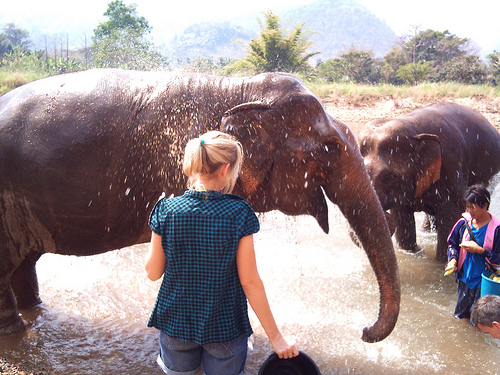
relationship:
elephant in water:
[355, 94, 491, 269] [11, 243, 499, 372]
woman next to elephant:
[139, 125, 303, 372] [5, 60, 404, 351]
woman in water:
[139, 125, 303, 372] [11, 243, 499, 372]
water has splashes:
[11, 243, 499, 372] [1, 299, 94, 374]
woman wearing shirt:
[139, 125, 303, 372] [145, 187, 259, 345]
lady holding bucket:
[436, 181, 499, 328] [476, 266, 499, 298]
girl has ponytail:
[139, 125, 303, 372] [178, 134, 212, 184]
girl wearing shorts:
[139, 125, 303, 372] [151, 332, 253, 374]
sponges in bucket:
[486, 267, 499, 281] [476, 266, 499, 298]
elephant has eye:
[355, 94, 491, 269] [379, 171, 395, 185]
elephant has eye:
[5, 60, 404, 351] [320, 138, 345, 157]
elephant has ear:
[355, 94, 491, 269] [412, 131, 449, 200]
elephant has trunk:
[5, 60, 404, 351] [326, 162, 407, 352]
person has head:
[139, 125, 303, 372] [171, 122, 253, 212]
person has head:
[436, 181, 499, 328] [456, 178, 495, 224]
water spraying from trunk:
[139, 92, 305, 151] [326, 162, 407, 352]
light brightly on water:
[268, 227, 364, 331] [11, 243, 499, 372]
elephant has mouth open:
[5, 60, 404, 351] [318, 183, 346, 235]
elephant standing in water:
[355, 94, 491, 269] [11, 243, 499, 372]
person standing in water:
[139, 125, 303, 372] [11, 243, 499, 372]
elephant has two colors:
[355, 94, 491, 269] [412, 131, 449, 200]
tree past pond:
[223, 8, 324, 76] [255, 215, 439, 362]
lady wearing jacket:
[436, 181, 499, 328] [440, 210, 499, 279]